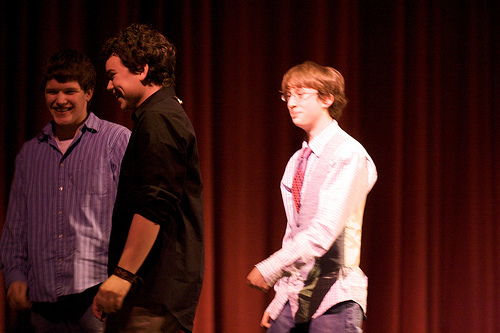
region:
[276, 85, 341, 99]
Glasses on a boy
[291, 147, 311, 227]
A red tie on a boy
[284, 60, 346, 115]
The boy's shaggy hair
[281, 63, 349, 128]
The head of a boy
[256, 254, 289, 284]
The left cut of the boy's shirt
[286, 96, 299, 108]
The nose of the boy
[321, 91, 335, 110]
An ear on the boy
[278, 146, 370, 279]
The left arm of the boy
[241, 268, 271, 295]
Left hand of the boy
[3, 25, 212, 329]
Two other boys smiling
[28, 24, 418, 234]
three young men on stage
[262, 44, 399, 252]
this boy has a tie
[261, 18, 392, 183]
this boy has red hair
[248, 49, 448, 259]
this boy has glasses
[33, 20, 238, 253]
two boys are laughing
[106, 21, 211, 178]
this boy wears a black shirt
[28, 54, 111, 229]
his shirt is button down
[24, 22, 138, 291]
his shirt is purple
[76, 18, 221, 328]
this boy has a wristband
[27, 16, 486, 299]
the curtains are red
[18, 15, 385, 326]
three young men in front of curtain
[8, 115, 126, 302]
striped button down shirt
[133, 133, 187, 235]
rolled up sleeve on shirt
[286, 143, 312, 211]
red tie on shirt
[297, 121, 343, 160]
tie knot under collar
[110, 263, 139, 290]
bracelet on man's wrist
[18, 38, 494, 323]
brown curtain behind men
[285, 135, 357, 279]
vest over dress shirt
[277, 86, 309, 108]
glasses on boy's face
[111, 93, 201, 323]
side of untucked black shirt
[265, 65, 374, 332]
young man in tie with amused expression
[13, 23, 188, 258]
two young men laughing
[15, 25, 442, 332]
group of business casual dressed boys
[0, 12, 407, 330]
three young men on a stage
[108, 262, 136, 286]
black and red wrist band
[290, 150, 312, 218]
red tie with multicolored dots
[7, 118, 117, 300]
blue and white button down with top collar unbuttoned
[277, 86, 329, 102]
boy is wearing glasses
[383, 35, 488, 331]
red curtains with deep shadow furrows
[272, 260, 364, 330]
shirt is not tucked into pants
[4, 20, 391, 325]
three teenagers on a stage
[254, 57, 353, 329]
a boy wearing glasses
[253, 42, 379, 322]
a boy wearing a red neck tie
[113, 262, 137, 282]
a brown leather band on a wrist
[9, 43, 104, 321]
a boy wearing a blue stripes shirt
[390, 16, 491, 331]
red curtains behind the boys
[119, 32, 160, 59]
curly brown hair on a head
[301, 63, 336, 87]
auburn hair on a head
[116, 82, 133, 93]
a dimple in a cheek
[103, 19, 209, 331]
a boy wearing a black shirt